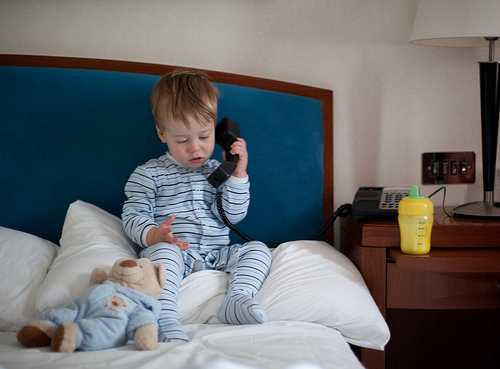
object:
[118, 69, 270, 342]
boy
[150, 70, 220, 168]
head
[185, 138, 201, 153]
nose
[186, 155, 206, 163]
mouth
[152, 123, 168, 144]
ear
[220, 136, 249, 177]
hand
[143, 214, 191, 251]
hand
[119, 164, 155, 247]
arm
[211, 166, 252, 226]
arm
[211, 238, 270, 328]
leg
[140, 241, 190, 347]
leg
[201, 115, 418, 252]
telephone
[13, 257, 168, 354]
teddy bear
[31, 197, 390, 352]
pillow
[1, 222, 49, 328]
pillow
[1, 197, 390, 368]
bed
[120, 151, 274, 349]
outfit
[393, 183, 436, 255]
cup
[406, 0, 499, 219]
lamp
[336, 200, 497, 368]
table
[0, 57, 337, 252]
headboard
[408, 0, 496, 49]
shade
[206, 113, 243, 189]
receiver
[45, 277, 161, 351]
pajamas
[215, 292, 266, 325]
left foot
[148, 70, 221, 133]
hair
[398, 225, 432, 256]
milk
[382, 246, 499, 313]
drawer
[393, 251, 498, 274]
wood